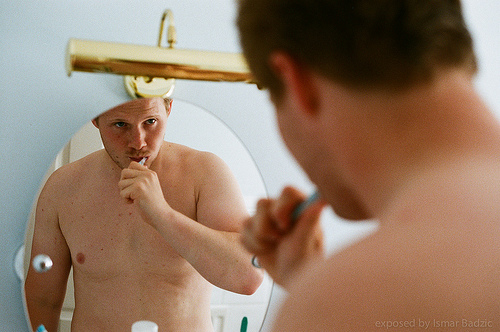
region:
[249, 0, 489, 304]
this is a man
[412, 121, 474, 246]
the man is light skinned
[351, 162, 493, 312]
the man is bare chested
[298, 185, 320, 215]
this is a toothbrush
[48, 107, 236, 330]
this is the image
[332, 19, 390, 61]
this is the hair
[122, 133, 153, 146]
this is a nose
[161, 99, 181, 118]
this is the ear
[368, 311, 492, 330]
this is a writing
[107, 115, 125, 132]
this is the eye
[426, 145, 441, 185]
part of a necka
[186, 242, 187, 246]
part of a mirror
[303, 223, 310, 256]
part of an arm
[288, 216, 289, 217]
part of a palm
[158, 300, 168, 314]
part of a stomach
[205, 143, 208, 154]
edge of a mirror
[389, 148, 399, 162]
part of a cheek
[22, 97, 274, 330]
reflection of a man brushing teeth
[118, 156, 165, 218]
a man's hand holding a toothbrush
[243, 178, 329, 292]
a man's hand holding a toothbrush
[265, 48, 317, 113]
ear of a man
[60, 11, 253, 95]
a golden bathroom light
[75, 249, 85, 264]
a man's nipple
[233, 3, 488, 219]
back of a man's head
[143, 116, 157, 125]
reflection of a man's eye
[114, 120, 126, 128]
reflection of a man's eye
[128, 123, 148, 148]
reflection of a man's nose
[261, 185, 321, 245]
the man brushes his teeth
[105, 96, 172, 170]
the man looks at himself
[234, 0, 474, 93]
the man has short hair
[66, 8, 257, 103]
the light fixture is gold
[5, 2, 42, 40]
part of the white wall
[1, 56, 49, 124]
part of the white wall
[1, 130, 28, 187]
part of the white wall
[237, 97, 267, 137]
part of the white wall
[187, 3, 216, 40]
part of the white wall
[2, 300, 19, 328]
part of the white wall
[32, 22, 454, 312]
a guy brushing his teeth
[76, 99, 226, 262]
he is looking in a mirror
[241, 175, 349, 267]
he is holding a toothbrush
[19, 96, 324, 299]
the mirror is round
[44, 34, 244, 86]
a light over the mirror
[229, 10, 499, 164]
the back of the man's head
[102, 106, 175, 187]
the ma's face looks focused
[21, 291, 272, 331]
objects near the mirror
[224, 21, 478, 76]
his hair is brown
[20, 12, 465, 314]
this guy is in his bathroom